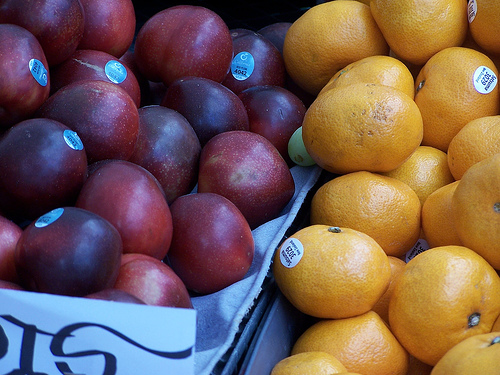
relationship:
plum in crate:
[9, 201, 124, 291] [7, 4, 316, 360]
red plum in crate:
[56, 80, 138, 149] [1, 144, 313, 366]